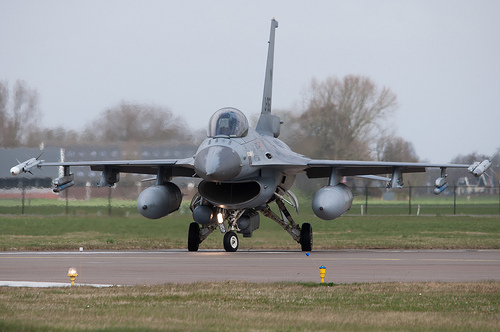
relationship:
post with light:
[318, 265, 326, 282] [318, 262, 326, 272]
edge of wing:
[433, 155, 472, 182] [267, 139, 484, 186]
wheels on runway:
[185, 218, 204, 254] [0, 239, 496, 289]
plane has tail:
[9, 14, 492, 254] [255, 9, 279, 129]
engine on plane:
[130, 182, 190, 232] [10, 10, 481, 271]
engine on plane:
[297, 166, 361, 234] [10, 10, 481, 271]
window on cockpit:
[208, 110, 258, 143] [194, 100, 262, 165]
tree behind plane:
[306, 69, 414, 163] [9, 14, 492, 254]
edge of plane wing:
[2, 150, 44, 179] [7, 156, 198, 179]